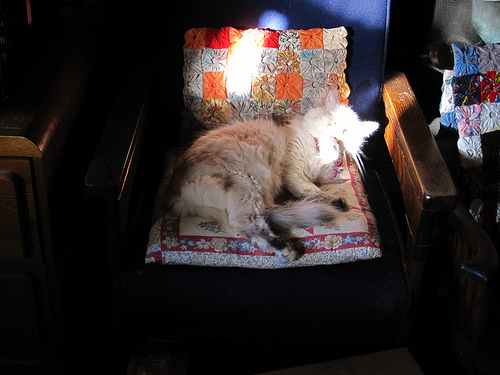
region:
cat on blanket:
[154, 78, 362, 278]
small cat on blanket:
[185, 85, 407, 245]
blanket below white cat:
[93, 191, 260, 305]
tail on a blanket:
[275, 197, 334, 227]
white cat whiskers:
[342, 150, 374, 172]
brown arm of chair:
[402, 103, 436, 198]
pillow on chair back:
[167, 25, 346, 111]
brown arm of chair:
[100, 78, 167, 212]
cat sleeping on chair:
[45, 75, 418, 283]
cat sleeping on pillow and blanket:
[145, 71, 414, 276]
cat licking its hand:
[71, 15, 446, 300]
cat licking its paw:
[139, 87, 439, 277]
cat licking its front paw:
[172, 77, 458, 313]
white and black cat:
[143, 78, 438, 299]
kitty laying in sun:
[153, 19, 468, 304]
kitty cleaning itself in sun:
[162, 39, 484, 339]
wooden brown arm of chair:
[384, 69, 489, 280]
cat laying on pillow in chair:
[127, 32, 402, 305]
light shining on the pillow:
[229, 30, 263, 95]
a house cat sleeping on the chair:
[166, 90, 374, 256]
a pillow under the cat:
[138, 175, 377, 262]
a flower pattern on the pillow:
[183, 27, 347, 129]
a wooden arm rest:
[379, 79, 455, 236]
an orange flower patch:
[276, 73, 302, 100]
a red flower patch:
[208, 28, 227, 48]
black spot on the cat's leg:
[261, 234, 303, 258]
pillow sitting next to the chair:
[448, 43, 498, 163]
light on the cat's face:
[319, 106, 370, 145]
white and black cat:
[163, 99, 370, 253]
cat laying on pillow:
[178, 104, 374, 259]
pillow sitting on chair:
[143, 145, 380, 264]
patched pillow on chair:
[182, 24, 349, 131]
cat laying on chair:
[160, 93, 380, 253]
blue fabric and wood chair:
[88, 0, 450, 361]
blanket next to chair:
[438, 44, 498, 173]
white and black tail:
[170, 194, 340, 232]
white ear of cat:
[325, 87, 338, 105]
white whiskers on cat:
[346, 145, 367, 172]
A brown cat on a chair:
[185, 81, 367, 217]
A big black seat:
[137, 13, 420, 322]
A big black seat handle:
[369, 65, 449, 230]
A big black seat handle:
[101, 87, 143, 212]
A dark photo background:
[11, 13, 134, 92]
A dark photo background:
[126, 17, 168, 102]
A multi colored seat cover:
[447, 45, 496, 145]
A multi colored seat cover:
[149, 213, 397, 272]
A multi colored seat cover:
[188, 37, 340, 119]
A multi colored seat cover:
[332, 160, 373, 256]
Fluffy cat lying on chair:
[161, 88, 383, 265]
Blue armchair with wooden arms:
[80, 0, 461, 330]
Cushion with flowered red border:
[143, 140, 385, 268]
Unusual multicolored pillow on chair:
[176, 23, 349, 143]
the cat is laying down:
[165, 81, 372, 237]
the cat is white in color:
[177, 92, 379, 257]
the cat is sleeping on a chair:
[170, 92, 373, 252]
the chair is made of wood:
[104, 5, 463, 370]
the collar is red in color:
[312, 134, 321, 150]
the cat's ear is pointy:
[325, 86, 336, 103]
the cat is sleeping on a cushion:
[152, 132, 383, 268]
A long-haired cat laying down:
[158, 86, 381, 264]